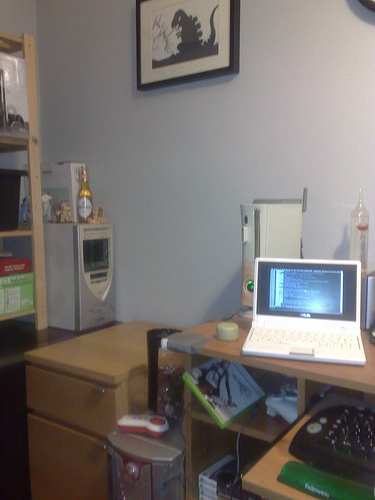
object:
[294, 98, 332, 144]
ground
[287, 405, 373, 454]
keyboard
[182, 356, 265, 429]
dvd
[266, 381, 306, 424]
controller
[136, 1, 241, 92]
picture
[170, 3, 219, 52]
dinosaur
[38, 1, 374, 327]
wall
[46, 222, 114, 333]
computer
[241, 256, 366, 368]
computer